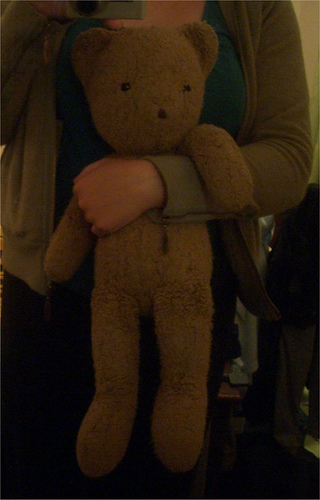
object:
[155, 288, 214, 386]
leg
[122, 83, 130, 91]
eye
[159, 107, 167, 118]
nose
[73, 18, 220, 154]
head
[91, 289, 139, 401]
leg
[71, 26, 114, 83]
ear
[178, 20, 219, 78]
ear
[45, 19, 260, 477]
bear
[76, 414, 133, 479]
foot bottom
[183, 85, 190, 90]
black eye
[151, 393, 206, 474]
foot bottom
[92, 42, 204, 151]
face